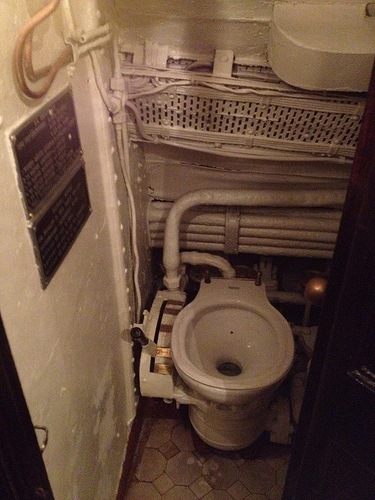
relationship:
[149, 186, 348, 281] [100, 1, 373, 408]
pipes on wall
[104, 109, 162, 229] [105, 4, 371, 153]
wires running along wall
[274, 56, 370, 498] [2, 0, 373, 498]
door leading to bathroom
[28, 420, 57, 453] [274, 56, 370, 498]
handle on door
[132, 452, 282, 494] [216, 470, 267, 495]
tile on floor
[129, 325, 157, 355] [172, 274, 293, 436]
handle beside toilet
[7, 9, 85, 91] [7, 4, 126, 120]
pipe on wall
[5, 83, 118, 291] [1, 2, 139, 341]
sign on wall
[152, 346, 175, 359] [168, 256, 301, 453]
plate by toilet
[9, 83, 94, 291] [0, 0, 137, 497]
plaque on side of wall